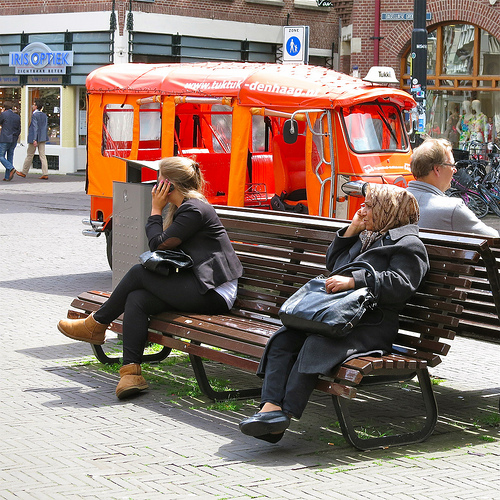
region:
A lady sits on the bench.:
[61, 155, 240, 401]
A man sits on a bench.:
[404, 148, 498, 237]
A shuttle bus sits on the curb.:
[85, 60, 441, 227]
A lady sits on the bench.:
[243, 184, 411, 443]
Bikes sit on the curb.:
[455, 152, 499, 203]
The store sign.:
[5, 43, 79, 76]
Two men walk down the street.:
[1, 100, 52, 182]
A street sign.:
[283, 23, 304, 60]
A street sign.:
[381, 10, 435, 20]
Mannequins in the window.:
[451, 95, 493, 156]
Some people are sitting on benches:
[36, 42, 476, 467]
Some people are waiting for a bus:
[75, 75, 482, 451]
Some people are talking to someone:
[91, 80, 476, 457]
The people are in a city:
[81, 87, 491, 493]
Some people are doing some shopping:
[95, 52, 490, 477]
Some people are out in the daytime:
[95, 63, 483, 479]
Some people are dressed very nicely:
[50, 95, 471, 456]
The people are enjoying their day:
[79, 52, 489, 473]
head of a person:
[143, 153, 213, 211]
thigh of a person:
[103, 242, 211, 307]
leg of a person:
[91, 260, 150, 325]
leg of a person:
[111, 305, 173, 371]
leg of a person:
[260, 336, 330, 405]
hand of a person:
[318, 274, 356, 294]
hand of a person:
[349, 208, 369, 223]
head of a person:
[352, 174, 424, 229]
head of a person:
[406, 126, 463, 203]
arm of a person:
[380, 243, 419, 322]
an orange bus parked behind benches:
[82, 61, 417, 276]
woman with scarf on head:
[359, 181, 416, 232]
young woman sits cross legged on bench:
[54, 155, 242, 402]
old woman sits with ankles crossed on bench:
[244, 175, 430, 455]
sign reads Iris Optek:
[8, 40, 73, 74]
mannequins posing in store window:
[457, 100, 487, 148]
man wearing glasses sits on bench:
[404, 140, 497, 241]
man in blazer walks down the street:
[17, 98, 49, 180]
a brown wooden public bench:
[62, 198, 478, 448]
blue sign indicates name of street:
[376, 7, 432, 22]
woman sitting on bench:
[55, 145, 220, 396]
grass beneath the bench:
[100, 340, 497, 445]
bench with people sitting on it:
[76, 194, 498, 421]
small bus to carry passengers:
[68, 51, 451, 271]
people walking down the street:
[0, 95, 57, 185]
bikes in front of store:
[439, 147, 499, 210]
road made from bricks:
[8, 189, 128, 481]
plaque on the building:
[381, 4, 434, 27]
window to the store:
[26, 83, 63, 138]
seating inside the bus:
[177, 140, 279, 190]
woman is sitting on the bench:
[234, 182, 425, 443]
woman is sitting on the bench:
[59, 153, 244, 399]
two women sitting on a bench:
[61, 155, 481, 444]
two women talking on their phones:
[55, 158, 482, 453]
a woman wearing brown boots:
[53, 155, 239, 405]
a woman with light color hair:
[55, 154, 240, 408]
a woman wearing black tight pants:
[55, 154, 242, 404]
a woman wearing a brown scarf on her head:
[240, 183, 425, 450]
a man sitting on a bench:
[398, 138, 498, 330]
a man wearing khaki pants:
[15, 98, 55, 184]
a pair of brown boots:
[55, 312, 152, 399]